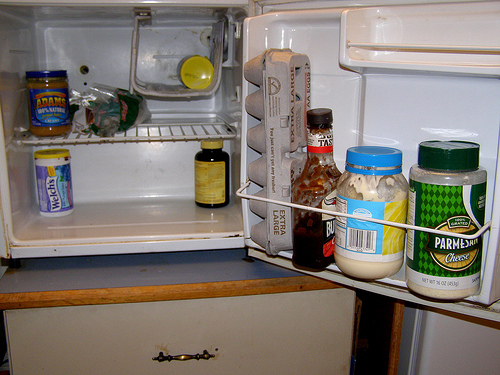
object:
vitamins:
[197, 153, 226, 209]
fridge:
[1, 2, 500, 313]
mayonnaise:
[330, 147, 406, 280]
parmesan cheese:
[407, 141, 487, 301]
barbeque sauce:
[291, 108, 336, 268]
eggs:
[242, 50, 305, 87]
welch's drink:
[33, 162, 71, 216]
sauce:
[26, 79, 69, 136]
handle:
[149, 348, 217, 363]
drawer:
[4, 288, 354, 375]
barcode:
[348, 228, 377, 253]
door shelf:
[238, 171, 487, 302]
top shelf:
[13, 115, 241, 146]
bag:
[67, 85, 154, 136]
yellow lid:
[200, 140, 224, 150]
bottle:
[193, 138, 230, 208]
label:
[193, 159, 226, 204]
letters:
[47, 173, 61, 212]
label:
[29, 85, 70, 127]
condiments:
[406, 137, 487, 300]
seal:
[0, 277, 340, 310]